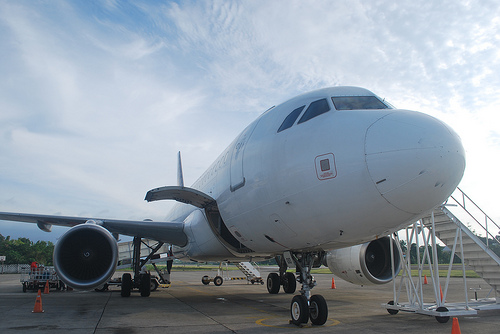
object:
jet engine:
[324, 235, 406, 282]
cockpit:
[276, 93, 391, 134]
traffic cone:
[44, 280, 50, 293]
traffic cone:
[32, 288, 43, 311]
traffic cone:
[331, 277, 336, 288]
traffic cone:
[424, 274, 428, 283]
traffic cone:
[451, 317, 461, 332]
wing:
[0, 200, 188, 253]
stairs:
[426, 174, 490, 306]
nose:
[352, 102, 477, 226]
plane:
[3, 52, 469, 323]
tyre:
[283, 270, 353, 329]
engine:
[50, 222, 125, 292]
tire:
[288, 292, 311, 325]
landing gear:
[283, 242, 330, 332]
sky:
[2, 3, 492, 123]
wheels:
[285, 287, 343, 324]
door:
[194, 80, 266, 221]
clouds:
[11, 17, 206, 121]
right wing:
[0, 209, 187, 249]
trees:
[431, 239, 448, 265]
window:
[323, 88, 388, 120]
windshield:
[275, 85, 465, 182]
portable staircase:
[382, 184, 499, 332]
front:
[263, 72, 486, 332]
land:
[4, 268, 495, 332]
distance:
[9, 243, 498, 273]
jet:
[0, 81, 467, 329]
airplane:
[2, 83, 467, 324]